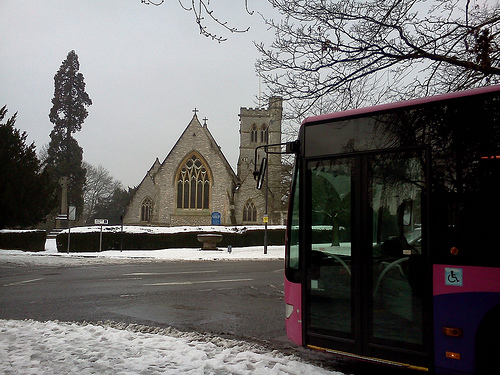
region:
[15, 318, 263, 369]
SNOW ON THE GROUND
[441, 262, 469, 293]
A HANDICAPPED SIGN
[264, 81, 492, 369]
A COMMUTER BUS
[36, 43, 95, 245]
A TREE IN THE DISTANCE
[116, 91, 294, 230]
A CHURCH IN THE BACKGROUND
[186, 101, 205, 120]
A CROSS ON TOP OF THE CHURCH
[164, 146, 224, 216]
A CHURCH WINDOW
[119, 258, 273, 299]
MARKINGS ON THE PAVEMENT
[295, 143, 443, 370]
CLOSED BUS DOORS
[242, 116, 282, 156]
TWO CHURCH WINDOWS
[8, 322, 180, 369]
A stack of snow by the road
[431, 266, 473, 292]
A sign showing the bus equipped for the disabled.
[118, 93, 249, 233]
A church building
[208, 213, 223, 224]
A blue entrance door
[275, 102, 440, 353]
A side of a bus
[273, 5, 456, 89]
Branches of trees with no leaves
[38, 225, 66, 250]
Steps to the church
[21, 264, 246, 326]
A wet road after the snow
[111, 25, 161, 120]
A gray sky in winter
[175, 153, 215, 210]
A classic gothic window panel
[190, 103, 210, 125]
Crosses on top of the church.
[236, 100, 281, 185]
A tower.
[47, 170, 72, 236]
A monument.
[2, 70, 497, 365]
A bus waiting at the intersection.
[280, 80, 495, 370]
The bus is pink and black.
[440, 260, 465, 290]
The handicap symbol.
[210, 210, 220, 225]
A blue sign in front of the church.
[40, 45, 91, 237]
A large conifer.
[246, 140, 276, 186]
A side mirror.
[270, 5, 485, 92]
The tree has no leaves on it.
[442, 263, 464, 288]
White wheelchair symbol on bus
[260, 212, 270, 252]
Yellow sign on dark pole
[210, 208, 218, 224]
Blue door on church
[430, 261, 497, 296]
Pink trim on bus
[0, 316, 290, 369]
White snow on ground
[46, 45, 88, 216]
Tall pine tree near church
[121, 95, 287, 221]
Tan stone church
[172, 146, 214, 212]
Large picture window on church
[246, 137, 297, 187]
Side view mirror on bus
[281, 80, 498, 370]
Pink and black bus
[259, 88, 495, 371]
Pink and blue bus on side of street.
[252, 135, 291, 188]
Side view mirror on bus.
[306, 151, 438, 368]
Doors to enter bus.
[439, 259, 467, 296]
A white wheel chair accessible sign.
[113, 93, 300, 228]
Brown church across street.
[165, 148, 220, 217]
Arched window in front of church.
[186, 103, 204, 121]
A cross on top of church.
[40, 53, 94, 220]
Tall tree growing next to church.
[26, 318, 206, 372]
Snow covered sidewalk.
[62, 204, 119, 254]
White traffic sign with black writing.